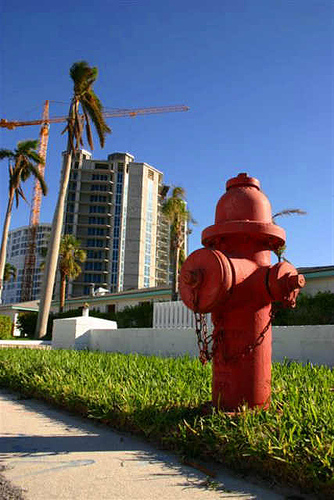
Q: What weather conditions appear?
A: It is cloudless.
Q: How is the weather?
A: It is cloudless.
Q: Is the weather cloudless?
A: Yes, it is cloudless.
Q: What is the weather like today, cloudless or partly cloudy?
A: It is cloudless.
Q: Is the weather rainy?
A: No, it is cloudless.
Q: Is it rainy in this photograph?
A: No, it is cloudless.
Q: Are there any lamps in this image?
A: No, there are no lamps.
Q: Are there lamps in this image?
A: No, there are no lamps.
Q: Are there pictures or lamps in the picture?
A: No, there are no lamps or pictures.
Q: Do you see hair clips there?
A: No, there are no hair clips.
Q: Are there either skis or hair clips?
A: No, there are no hair clips or skis.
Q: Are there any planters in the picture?
A: No, there are no planters.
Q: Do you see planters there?
A: No, there are no planters.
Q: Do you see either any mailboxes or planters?
A: No, there are no planters or mailboxes.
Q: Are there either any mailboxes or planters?
A: No, there are no planters or mailboxes.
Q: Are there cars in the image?
A: No, there are no cars.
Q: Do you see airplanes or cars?
A: No, there are no cars or airplanes.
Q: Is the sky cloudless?
A: Yes, the sky is cloudless.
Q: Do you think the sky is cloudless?
A: Yes, the sky is cloudless.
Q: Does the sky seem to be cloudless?
A: Yes, the sky is cloudless.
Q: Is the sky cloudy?
A: No, the sky is cloudless.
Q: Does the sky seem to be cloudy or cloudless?
A: The sky is cloudless.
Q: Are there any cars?
A: No, there are no cars.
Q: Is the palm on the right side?
A: No, the palm is on the left of the image.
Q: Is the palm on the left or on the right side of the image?
A: The palm is on the left of the image.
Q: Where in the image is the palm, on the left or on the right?
A: The palm is on the left of the image.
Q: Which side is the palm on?
A: The palm is on the left of the image.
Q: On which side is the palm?
A: The palm is on the left of the image.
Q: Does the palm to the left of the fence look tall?
A: Yes, the palm is tall.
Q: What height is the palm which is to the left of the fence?
A: The palm tree is tall.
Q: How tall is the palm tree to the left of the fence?
A: The palm is tall.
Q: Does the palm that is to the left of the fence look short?
A: No, the palm is tall.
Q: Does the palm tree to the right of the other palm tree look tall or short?
A: The palm is tall.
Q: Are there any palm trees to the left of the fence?
A: Yes, there is a palm tree to the left of the fence.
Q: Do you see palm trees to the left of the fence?
A: Yes, there is a palm tree to the left of the fence.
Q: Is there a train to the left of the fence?
A: No, there is a palm tree to the left of the fence.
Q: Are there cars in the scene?
A: No, there are no cars.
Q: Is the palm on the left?
A: Yes, the palm is on the left of the image.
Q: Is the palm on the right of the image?
A: No, the palm is on the left of the image.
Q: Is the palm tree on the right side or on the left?
A: The palm tree is on the left of the image.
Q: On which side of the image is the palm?
A: The palm is on the left of the image.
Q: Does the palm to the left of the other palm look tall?
A: Yes, the palm tree is tall.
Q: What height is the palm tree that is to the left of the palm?
A: The palm tree is tall.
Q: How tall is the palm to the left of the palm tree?
A: The palm tree is tall.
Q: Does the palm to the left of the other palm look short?
A: No, the palm tree is tall.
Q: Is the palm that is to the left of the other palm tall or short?
A: The palm tree is tall.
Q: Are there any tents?
A: No, there are no tents.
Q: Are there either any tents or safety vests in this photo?
A: No, there are no tents or safety vests.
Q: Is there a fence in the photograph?
A: Yes, there is a fence.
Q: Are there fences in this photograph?
A: Yes, there is a fence.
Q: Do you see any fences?
A: Yes, there is a fence.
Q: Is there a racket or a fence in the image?
A: Yes, there is a fence.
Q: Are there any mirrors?
A: No, there are no mirrors.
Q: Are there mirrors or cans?
A: No, there are no mirrors or cans.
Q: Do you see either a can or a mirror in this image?
A: No, there are no mirrors or cans.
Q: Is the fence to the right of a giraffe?
A: No, the fence is to the right of a palm tree.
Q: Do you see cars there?
A: No, there are no cars.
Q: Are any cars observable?
A: No, there are no cars.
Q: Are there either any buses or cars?
A: No, there are no cars or buses.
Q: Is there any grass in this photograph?
A: Yes, there is grass.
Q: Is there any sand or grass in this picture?
A: Yes, there is grass.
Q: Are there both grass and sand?
A: No, there is grass but no sand.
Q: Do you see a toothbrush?
A: No, there are no toothbrushes.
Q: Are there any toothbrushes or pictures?
A: No, there are no toothbrushes or pictures.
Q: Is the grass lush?
A: Yes, the grass is lush.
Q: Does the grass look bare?
A: No, the grass is lush.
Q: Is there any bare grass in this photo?
A: No, there is grass but it is lush.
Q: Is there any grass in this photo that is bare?
A: No, there is grass but it is lush.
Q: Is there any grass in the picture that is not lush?
A: No, there is grass but it is lush.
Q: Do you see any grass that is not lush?
A: No, there is grass but it is lush.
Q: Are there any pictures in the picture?
A: No, there are no pictures.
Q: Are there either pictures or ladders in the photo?
A: No, there are no pictures or ladders.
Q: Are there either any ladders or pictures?
A: No, there are no pictures or ladders.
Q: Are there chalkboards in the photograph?
A: No, there are no chalkboards.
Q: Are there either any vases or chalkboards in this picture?
A: No, there are no chalkboards or vases.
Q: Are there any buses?
A: No, there are no buses.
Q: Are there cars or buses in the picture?
A: No, there are no buses or cars.